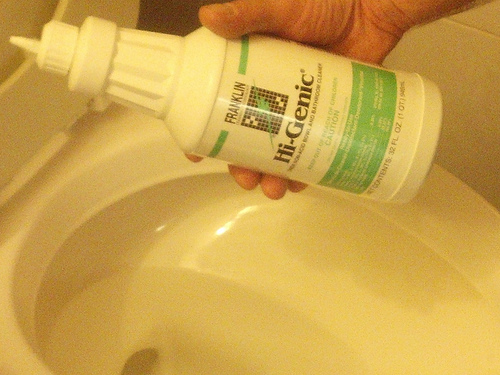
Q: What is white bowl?
A: A toilet.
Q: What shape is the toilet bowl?
A: Oval.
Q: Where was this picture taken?
A: In a bathroom.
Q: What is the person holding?
A: A bottle.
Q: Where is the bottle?
A: In the person's hand.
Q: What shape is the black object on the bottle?
A: A square.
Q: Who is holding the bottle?
A: A person.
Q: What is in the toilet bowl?
A: Water.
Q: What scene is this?
A: Indoor.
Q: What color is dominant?
A: White.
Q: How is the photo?
A: Clear.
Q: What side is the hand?
A: Right.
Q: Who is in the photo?
A: A person.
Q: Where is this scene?
A: Bathroom.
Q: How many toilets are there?
A: One.